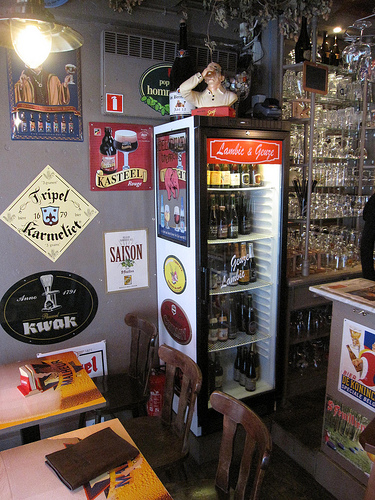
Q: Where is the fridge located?
A: Against the wall.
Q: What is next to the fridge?
A: A shelf.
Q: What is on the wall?
A: Beer Advertisement.